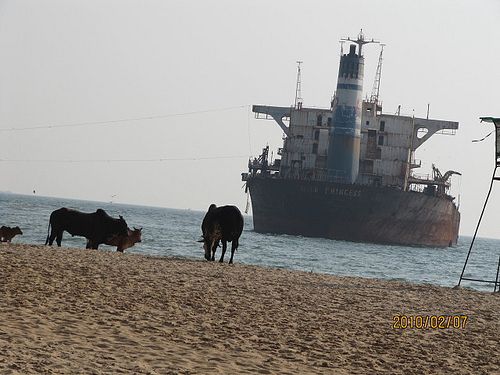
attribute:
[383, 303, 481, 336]
number — yellow print style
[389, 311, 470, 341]
number — yellow print style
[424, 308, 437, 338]
number — yellow, print style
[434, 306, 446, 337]
number — print style, yellow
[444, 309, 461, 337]
number — yellow, print style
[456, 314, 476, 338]
number — print style, yellow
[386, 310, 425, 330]
number — yellow, print style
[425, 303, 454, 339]
number — print style, yellow